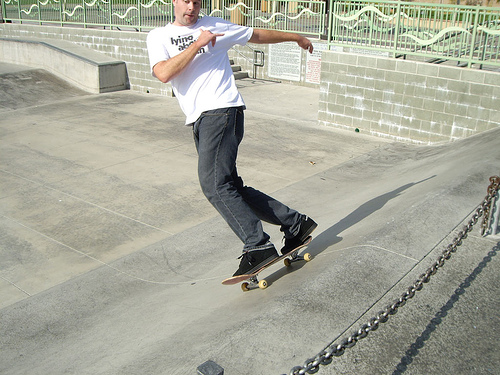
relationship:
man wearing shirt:
[128, 0, 339, 274] [138, 15, 258, 131]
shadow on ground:
[234, 168, 442, 298] [1, 126, 499, 375]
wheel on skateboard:
[238, 279, 251, 298] [212, 231, 320, 297]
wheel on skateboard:
[255, 277, 272, 293] [212, 231, 320, 297]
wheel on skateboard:
[277, 254, 297, 271] [212, 231, 320, 297]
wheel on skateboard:
[300, 250, 314, 265] [212, 231, 320, 297]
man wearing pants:
[128, 0, 339, 274] [183, 100, 303, 258]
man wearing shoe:
[128, 0, 339, 274] [224, 232, 282, 287]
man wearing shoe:
[128, 0, 339, 274] [276, 211, 322, 256]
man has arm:
[128, 0, 339, 274] [138, 24, 224, 90]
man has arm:
[128, 0, 339, 274] [216, 20, 325, 59]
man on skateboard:
[128, 0, 339, 274] [212, 231, 320, 297]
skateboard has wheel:
[212, 231, 320, 297] [238, 279, 251, 298]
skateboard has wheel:
[212, 231, 320, 297] [255, 277, 272, 293]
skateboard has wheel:
[212, 231, 320, 297] [277, 254, 297, 271]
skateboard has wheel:
[212, 231, 320, 297] [300, 250, 314, 265]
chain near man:
[203, 169, 498, 374] [128, 0, 339, 274]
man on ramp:
[128, 0, 339, 274] [1, 126, 499, 375]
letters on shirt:
[165, 30, 212, 65] [138, 15, 258, 131]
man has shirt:
[128, 0, 339, 274] [138, 15, 258, 131]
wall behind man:
[0, 19, 496, 133] [128, 0, 339, 274]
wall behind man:
[0, 19, 185, 106] [128, 0, 339, 274]